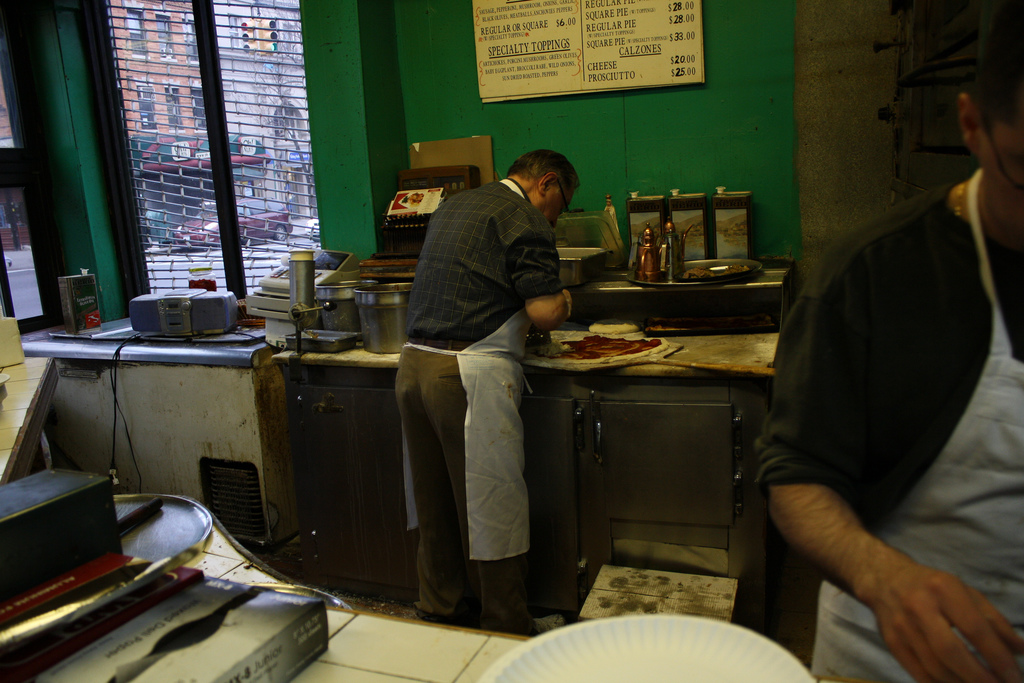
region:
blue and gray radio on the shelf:
[129, 281, 235, 336]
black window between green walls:
[119, 2, 315, 301]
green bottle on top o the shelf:
[651, 215, 684, 283]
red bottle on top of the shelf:
[637, 221, 657, 282]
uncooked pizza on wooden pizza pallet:
[531, 325, 668, 358]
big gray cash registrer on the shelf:
[244, 249, 358, 349]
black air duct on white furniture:
[196, 452, 260, 541]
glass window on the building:
[130, 85, 163, 130]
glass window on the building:
[163, 79, 186, 136]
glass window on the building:
[153, 10, 172, 58]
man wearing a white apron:
[756, 13, 1022, 678]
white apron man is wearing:
[397, 303, 535, 561]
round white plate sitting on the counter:
[476, 610, 825, 680]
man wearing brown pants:
[396, 146, 581, 634]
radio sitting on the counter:
[130, 285, 242, 346]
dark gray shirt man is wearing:
[400, 179, 565, 348]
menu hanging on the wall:
[465, 0, 707, 100]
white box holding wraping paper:
[38, 567, 324, 676]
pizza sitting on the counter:
[520, 329, 669, 368]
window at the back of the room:
[95, 0, 336, 291]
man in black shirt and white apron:
[397, 146, 581, 628]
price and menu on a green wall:
[462, 0, 719, 108]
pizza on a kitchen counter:
[530, 328, 674, 373]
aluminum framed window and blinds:
[75, 0, 331, 294]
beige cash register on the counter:
[240, 243, 358, 342]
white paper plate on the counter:
[473, 606, 816, 679]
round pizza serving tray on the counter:
[620, 217, 764, 290]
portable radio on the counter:
[125, 288, 242, 343]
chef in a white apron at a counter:
[759, 15, 1020, 677]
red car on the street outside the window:
[111, 0, 317, 282]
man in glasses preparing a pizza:
[387, 145, 575, 636]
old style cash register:
[361, 159, 492, 274]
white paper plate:
[462, 601, 832, 679]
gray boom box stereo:
[123, 282, 247, 340]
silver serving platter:
[618, 218, 775, 286]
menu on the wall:
[460, 1, 723, 106]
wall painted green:
[0, 0, 806, 324]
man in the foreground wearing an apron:
[747, 13, 1020, 680]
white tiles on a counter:
[272, 597, 547, 680]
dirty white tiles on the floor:
[572, 550, 747, 646]